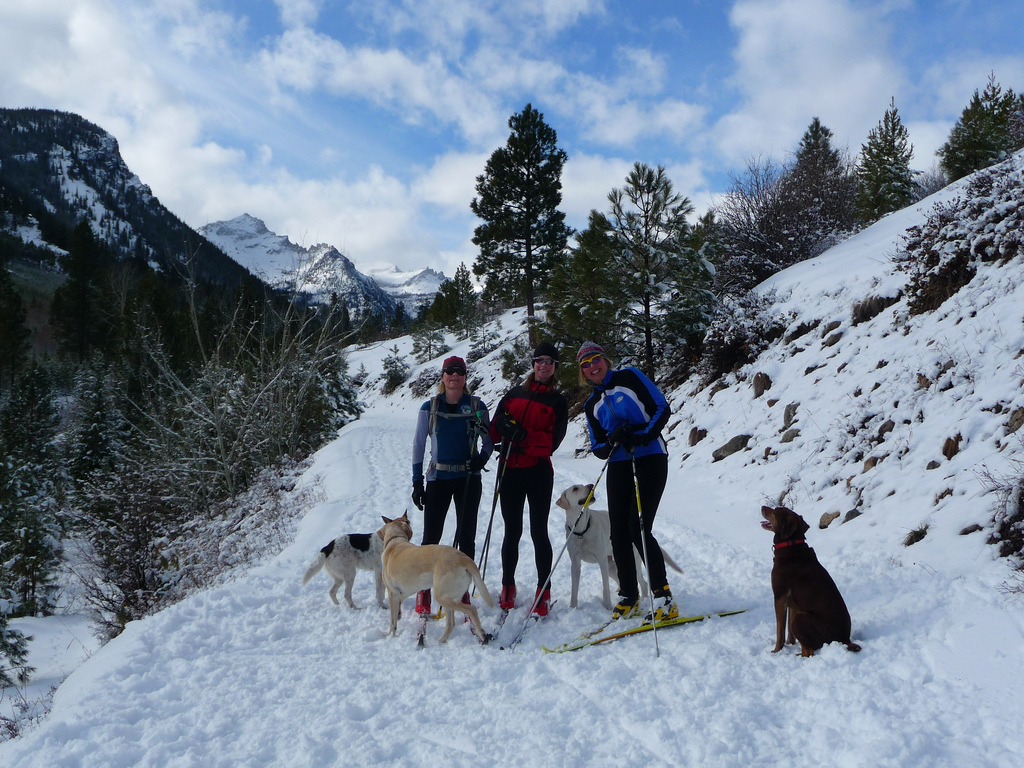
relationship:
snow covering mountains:
[2, 143, 1024, 766] [191, 212, 470, 327]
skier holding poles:
[503, 340, 565, 623] [469, 440, 509, 624]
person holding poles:
[573, 337, 677, 628] [527, 440, 651, 624]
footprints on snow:
[77, 399, 1023, 763] [2, 143, 1024, 766]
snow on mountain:
[1, 179, 1013, 767] [2, 106, 281, 313]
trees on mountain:
[2, 75, 1020, 639] [2, 106, 281, 313]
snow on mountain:
[1, 179, 1013, 767] [178, 212, 454, 314]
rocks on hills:
[694, 239, 1012, 537] [304, 159, 1013, 767]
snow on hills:
[1, 179, 1013, 767] [304, 159, 1013, 767]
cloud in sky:
[244, 0, 764, 225] [6, 0, 1022, 304]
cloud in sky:
[0, 4, 425, 242] [6, 0, 1022, 304]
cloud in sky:
[707, 0, 1012, 198] [6, 0, 1022, 304]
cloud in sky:
[483, 45, 708, 143] [6, 0, 1022, 304]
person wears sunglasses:
[408, 351, 495, 551] [442, 361, 471, 372]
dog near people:
[555, 477, 682, 605] [487, 339, 570, 631]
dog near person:
[758, 496, 869, 662] [408, 354, 496, 615]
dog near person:
[306, 525, 384, 618] [573, 337, 677, 628]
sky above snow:
[6, 0, 1022, 304] [18, 128, 149, 264]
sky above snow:
[6, 0, 1022, 304] [209, 219, 328, 290]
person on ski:
[578, 338, 678, 621] [563, 605, 751, 650]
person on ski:
[578, 338, 678, 621] [549, 594, 633, 651]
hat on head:
[531, 342, 558, 362] [527, 343, 567, 395]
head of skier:
[527, 343, 567, 395] [484, 344, 569, 618]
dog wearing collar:
[758, 505, 863, 657] [773, 534, 808, 557]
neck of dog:
[565, 504, 594, 539] [556, 481, 681, 614]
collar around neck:
[563, 503, 598, 542] [565, 504, 594, 539]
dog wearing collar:
[758, 505, 863, 657] [776, 532, 808, 553]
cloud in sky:
[6, 0, 436, 266] [6, 0, 1022, 304]